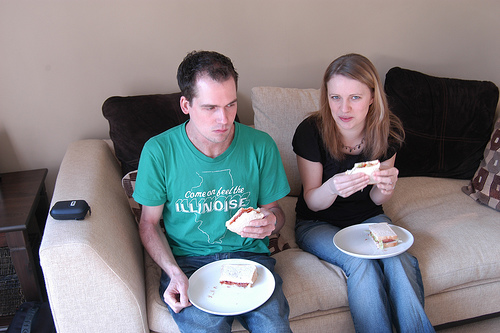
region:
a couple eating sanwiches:
[131, 45, 439, 330]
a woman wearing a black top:
[283, 45, 460, 328]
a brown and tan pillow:
[461, 142, 498, 203]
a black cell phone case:
[46, 193, 112, 222]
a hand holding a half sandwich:
[243, 203, 282, 238]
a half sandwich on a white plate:
[329, 222, 431, 267]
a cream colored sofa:
[423, 186, 484, 271]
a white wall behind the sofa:
[134, 3, 469, 37]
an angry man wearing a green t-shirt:
[157, 60, 299, 331]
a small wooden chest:
[13, 174, 40, 296]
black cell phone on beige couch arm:
[46, 189, 94, 224]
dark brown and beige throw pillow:
[461, 121, 496, 215]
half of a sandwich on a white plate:
[186, 253, 278, 310]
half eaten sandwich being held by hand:
[228, 205, 277, 245]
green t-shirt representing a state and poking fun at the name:
[168, 174, 228, 231]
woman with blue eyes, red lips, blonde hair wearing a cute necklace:
[316, 58, 390, 155]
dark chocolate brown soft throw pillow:
[404, 75, 471, 173]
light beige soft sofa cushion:
[426, 203, 493, 286]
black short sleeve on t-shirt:
[291, 119, 325, 161]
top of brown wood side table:
[1, 168, 36, 225]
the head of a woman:
[318, 53, 379, 131]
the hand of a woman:
[329, 165, 374, 203]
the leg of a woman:
[294, 217, 399, 332]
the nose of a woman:
[338, 93, 353, 114]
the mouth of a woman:
[334, 112, 357, 126]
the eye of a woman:
[346, 90, 364, 105]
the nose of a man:
[212, 105, 229, 127]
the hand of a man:
[157, 266, 197, 318]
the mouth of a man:
[207, 123, 233, 139]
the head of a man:
[169, 43, 243, 155]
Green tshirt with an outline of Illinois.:
[171, 170, 271, 250]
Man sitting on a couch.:
[132, 47, 302, 332]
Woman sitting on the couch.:
[293, 50, 433, 331]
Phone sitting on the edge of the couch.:
[48, 194, 91, 221]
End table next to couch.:
[1, 161, 51, 328]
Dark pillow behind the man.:
[100, 86, 245, 173]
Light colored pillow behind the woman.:
[248, 83, 373, 198]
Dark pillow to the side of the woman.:
[379, 61, 497, 184]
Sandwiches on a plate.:
[213, 160, 408, 290]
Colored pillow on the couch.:
[461, 108, 497, 218]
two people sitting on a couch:
[92, 45, 454, 327]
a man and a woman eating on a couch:
[139, 45, 441, 324]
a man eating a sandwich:
[140, 38, 298, 330]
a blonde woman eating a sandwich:
[292, 52, 452, 322]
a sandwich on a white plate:
[193, 248, 274, 309]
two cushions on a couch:
[393, 66, 499, 203]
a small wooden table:
[1, 156, 50, 308]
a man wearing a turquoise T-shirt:
[151, 122, 272, 252]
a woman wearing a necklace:
[328, 132, 383, 158]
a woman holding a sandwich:
[333, 156, 401, 211]